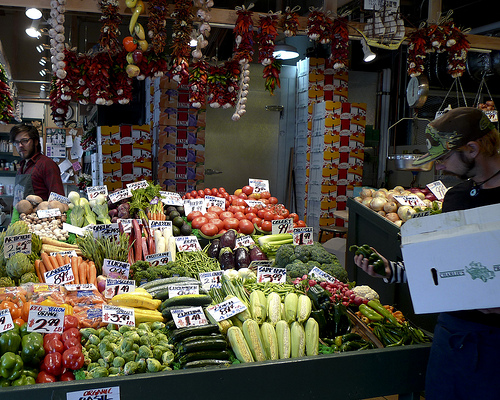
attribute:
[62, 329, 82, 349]
peppers — red, green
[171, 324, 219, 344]
cucumbers — green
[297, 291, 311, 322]
corn — yellow, fresh, vegetable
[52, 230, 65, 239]
onions — yellow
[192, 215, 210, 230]
tomatoes — red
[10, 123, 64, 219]
man — produce clerk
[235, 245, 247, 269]
eggplant — purple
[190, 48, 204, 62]
garlic — hanging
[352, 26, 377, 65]
lights — on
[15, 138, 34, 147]
glasses — black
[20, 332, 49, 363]
peppers — green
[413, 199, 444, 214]
artichokes — green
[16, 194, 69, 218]
mushrooms — large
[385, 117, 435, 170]
basket — metal